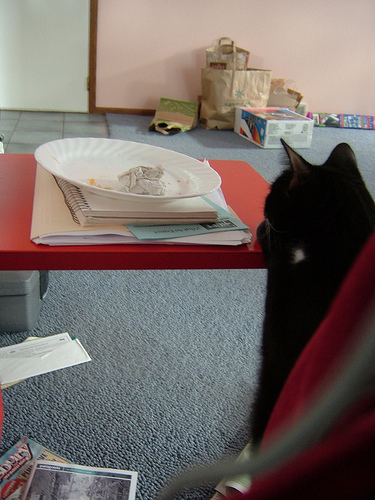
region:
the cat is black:
[247, 129, 370, 310]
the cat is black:
[255, 193, 363, 455]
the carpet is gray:
[92, 328, 161, 388]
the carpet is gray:
[133, 305, 206, 389]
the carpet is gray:
[69, 257, 153, 387]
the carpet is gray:
[146, 315, 248, 472]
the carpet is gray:
[99, 307, 195, 460]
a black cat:
[239, 135, 373, 475]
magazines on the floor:
[0, 431, 140, 498]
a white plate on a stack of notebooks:
[33, 127, 239, 243]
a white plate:
[25, 132, 225, 200]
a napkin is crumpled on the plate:
[109, 161, 177, 195]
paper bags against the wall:
[150, 33, 308, 134]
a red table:
[3, 138, 304, 279]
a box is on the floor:
[227, 100, 319, 148]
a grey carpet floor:
[12, 102, 372, 497]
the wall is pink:
[99, 1, 373, 115]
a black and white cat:
[247, 140, 373, 453]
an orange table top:
[0, 154, 275, 267]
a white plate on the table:
[33, 136, 223, 203]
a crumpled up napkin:
[116, 161, 167, 196]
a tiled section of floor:
[0, 111, 104, 151]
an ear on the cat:
[278, 138, 309, 173]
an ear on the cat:
[325, 143, 358, 170]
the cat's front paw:
[254, 217, 290, 257]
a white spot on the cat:
[291, 244, 304, 264]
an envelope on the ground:
[0, 330, 92, 384]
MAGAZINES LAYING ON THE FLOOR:
[0, 432, 144, 498]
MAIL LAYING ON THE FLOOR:
[0, 329, 90, 389]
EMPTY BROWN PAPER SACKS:
[146, 36, 274, 130]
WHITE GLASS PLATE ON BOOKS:
[30, 136, 220, 200]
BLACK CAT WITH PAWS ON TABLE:
[250, 137, 374, 432]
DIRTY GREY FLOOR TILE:
[7, 112, 88, 144]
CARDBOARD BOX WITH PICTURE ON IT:
[232, 104, 326, 150]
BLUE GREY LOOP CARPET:
[135, 359, 214, 451]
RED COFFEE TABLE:
[1, 144, 290, 284]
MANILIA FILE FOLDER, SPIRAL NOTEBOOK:
[28, 150, 88, 246]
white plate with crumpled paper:
[34, 136, 221, 197]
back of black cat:
[255, 141, 372, 440]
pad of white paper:
[67, 187, 217, 225]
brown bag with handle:
[207, 37, 248, 67]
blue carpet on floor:
[3, 113, 372, 498]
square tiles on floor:
[2, 111, 107, 156]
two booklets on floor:
[0, 437, 139, 498]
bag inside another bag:
[198, 35, 272, 129]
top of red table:
[0, 153, 289, 268]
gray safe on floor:
[1, 269, 47, 331]